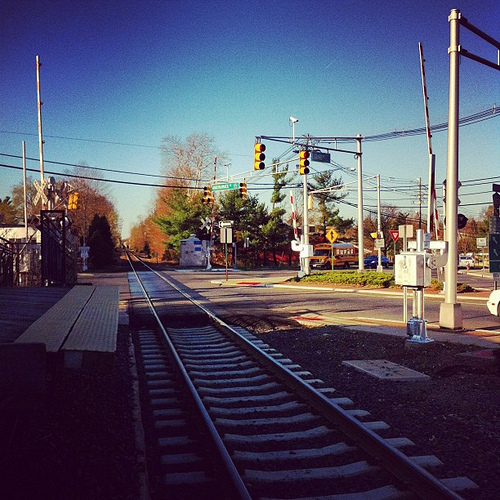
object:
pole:
[437, 3, 460, 332]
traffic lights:
[254, 142, 309, 175]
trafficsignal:
[253, 135, 267, 170]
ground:
[363, 143, 470, 233]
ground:
[405, 192, 420, 247]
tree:
[256, 170, 300, 264]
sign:
[325, 229, 338, 245]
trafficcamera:
[289, 117, 299, 138]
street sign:
[489, 235, 500, 272]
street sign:
[487, 184, 500, 235]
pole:
[494, 275, 499, 292]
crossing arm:
[289, 188, 306, 241]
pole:
[35, 51, 45, 183]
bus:
[311, 239, 357, 267]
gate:
[411, 40, 441, 252]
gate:
[32, 54, 46, 239]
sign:
[210, 182, 240, 191]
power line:
[3, 146, 490, 232]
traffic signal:
[298, 149, 310, 176]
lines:
[9, 93, 482, 240]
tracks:
[135, 280, 325, 465]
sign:
[32, 178, 51, 206]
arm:
[290, 190, 298, 243]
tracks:
[122, 249, 478, 499]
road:
[81, 259, 279, 338]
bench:
[19, 284, 118, 354]